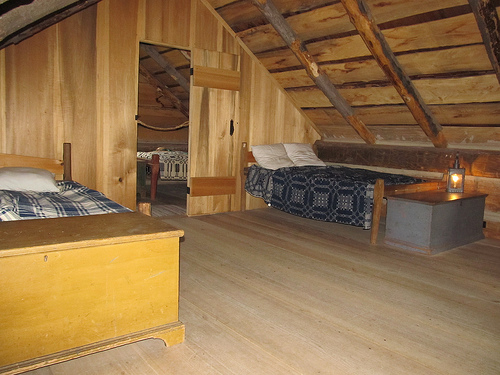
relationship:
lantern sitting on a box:
[447, 155, 466, 194] [383, 189, 488, 258]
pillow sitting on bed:
[252, 144, 296, 170] [249, 164, 428, 230]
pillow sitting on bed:
[283, 142, 325, 166] [249, 164, 428, 230]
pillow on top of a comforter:
[1, 167, 58, 194] [1, 176, 132, 221]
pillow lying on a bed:
[252, 144, 296, 170] [249, 164, 428, 230]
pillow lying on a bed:
[283, 142, 325, 166] [249, 164, 428, 230]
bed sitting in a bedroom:
[249, 164, 428, 230] [2, 1, 500, 374]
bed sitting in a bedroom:
[1, 180, 132, 223] [2, 1, 500, 374]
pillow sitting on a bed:
[1, 167, 58, 194] [1, 180, 132, 223]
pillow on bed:
[252, 144, 296, 170] [249, 164, 428, 230]